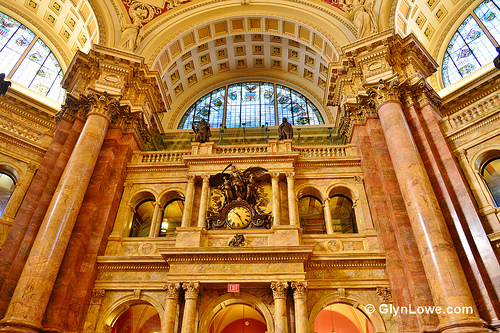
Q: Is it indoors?
A: Yes, it is indoors.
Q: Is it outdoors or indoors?
A: It is indoors.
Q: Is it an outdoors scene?
A: No, it is indoors.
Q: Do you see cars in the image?
A: No, there are no cars.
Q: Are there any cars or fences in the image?
A: No, there are no cars or fences.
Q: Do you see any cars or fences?
A: No, there are no cars or fences.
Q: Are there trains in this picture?
A: No, there are no trains.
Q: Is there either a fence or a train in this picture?
A: No, there are no trains or fences.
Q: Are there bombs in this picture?
A: No, there are no bombs.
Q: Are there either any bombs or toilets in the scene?
A: No, there are no bombs or toilets.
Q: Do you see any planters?
A: No, there are no planters.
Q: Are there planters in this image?
A: No, there are no planters.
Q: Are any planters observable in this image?
A: No, there are no planters.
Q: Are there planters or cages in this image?
A: No, there are no planters or cages.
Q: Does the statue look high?
A: Yes, the statue is high.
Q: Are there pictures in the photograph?
A: No, there are no pictures.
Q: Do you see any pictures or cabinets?
A: No, there are no pictures or cabinets.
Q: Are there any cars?
A: No, there are no cars.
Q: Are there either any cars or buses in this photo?
A: No, there are no cars or buses.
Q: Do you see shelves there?
A: No, there are no shelves.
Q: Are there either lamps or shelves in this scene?
A: No, there are no shelves or lamps.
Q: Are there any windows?
A: Yes, there is a window.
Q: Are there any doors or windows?
A: Yes, there is a window.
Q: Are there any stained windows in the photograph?
A: Yes, there is a stained window.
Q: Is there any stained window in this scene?
A: Yes, there is a stained window.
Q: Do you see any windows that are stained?
A: Yes, there is a window that is stained.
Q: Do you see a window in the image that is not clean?
A: Yes, there is a stained window.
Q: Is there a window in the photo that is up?
A: Yes, there is a window that is up.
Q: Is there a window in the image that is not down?
A: Yes, there is a window that is up.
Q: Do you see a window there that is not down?
A: Yes, there is a window that is up .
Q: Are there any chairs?
A: No, there are no chairs.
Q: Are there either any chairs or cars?
A: No, there are no chairs or cars.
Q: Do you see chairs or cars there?
A: No, there are no chairs or cars.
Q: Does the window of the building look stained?
A: Yes, the window is stained.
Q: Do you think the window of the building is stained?
A: Yes, the window is stained.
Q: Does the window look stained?
A: Yes, the window is stained.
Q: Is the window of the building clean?
A: No, the window is stained.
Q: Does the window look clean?
A: No, the window is stained.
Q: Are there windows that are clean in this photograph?
A: No, there is a window but it is stained.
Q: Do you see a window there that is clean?
A: No, there is a window but it is stained.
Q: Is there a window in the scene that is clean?
A: No, there is a window but it is stained.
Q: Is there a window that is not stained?
A: No, there is a window but it is stained.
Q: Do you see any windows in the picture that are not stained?
A: No, there is a window but it is stained.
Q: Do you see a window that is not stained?
A: No, there is a window but it is stained.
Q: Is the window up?
A: Yes, the window is up.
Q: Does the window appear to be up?
A: Yes, the window is up.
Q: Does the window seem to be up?
A: Yes, the window is up.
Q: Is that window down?
A: No, the window is up.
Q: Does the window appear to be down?
A: No, the window is up.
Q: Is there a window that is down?
A: No, there is a window but it is up.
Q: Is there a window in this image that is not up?
A: No, there is a window but it is up.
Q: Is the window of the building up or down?
A: The window is up.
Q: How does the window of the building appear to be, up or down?
A: The window is up.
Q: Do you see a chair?
A: No, there are no chairs.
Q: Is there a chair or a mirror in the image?
A: No, there are no chairs or mirrors.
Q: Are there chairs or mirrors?
A: No, there are no chairs or mirrors.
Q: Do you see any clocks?
A: Yes, there is a clock.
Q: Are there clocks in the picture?
A: Yes, there is a clock.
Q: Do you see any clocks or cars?
A: Yes, there is a clock.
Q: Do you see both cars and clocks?
A: No, there is a clock but no cars.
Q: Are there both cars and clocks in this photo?
A: No, there is a clock but no cars.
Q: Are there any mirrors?
A: No, there are no mirrors.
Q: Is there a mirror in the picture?
A: No, there are no mirrors.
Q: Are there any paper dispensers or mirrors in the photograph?
A: No, there are no mirrors or paper dispensers.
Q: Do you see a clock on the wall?
A: Yes, there is a clock on the wall.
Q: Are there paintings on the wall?
A: No, there is a clock on the wall.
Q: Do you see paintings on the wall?
A: No, there is a clock on the wall.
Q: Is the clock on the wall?
A: Yes, the clock is on the wall.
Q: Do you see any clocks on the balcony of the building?
A: Yes, there is a clock on the balcony.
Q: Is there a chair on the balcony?
A: No, there is a clock on the balcony.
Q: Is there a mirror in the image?
A: No, there are no mirrors.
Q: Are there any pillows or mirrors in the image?
A: No, there are no mirrors or pillows.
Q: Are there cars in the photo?
A: No, there are no cars.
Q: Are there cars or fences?
A: No, there are no cars or fences.